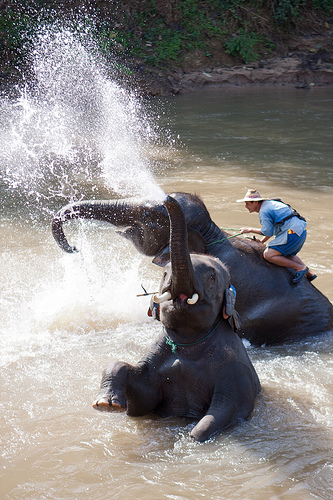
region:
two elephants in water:
[35, 184, 330, 442]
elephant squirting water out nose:
[0, 5, 271, 441]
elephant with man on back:
[38, 184, 332, 344]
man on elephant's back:
[238, 180, 319, 283]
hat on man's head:
[237, 187, 270, 203]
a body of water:
[187, 98, 328, 172]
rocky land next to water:
[185, 65, 331, 88]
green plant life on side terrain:
[146, 22, 205, 61]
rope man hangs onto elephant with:
[208, 220, 243, 241]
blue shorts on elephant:
[273, 232, 308, 252]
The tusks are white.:
[147, 289, 206, 312]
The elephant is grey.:
[112, 229, 260, 437]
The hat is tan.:
[232, 179, 270, 209]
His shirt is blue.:
[254, 200, 303, 245]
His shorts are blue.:
[263, 219, 306, 255]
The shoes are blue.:
[287, 264, 316, 284]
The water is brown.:
[10, 363, 332, 497]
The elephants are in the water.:
[43, 170, 312, 438]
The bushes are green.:
[7, 4, 322, 64]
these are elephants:
[10, 101, 326, 355]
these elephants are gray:
[78, 190, 246, 395]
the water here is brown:
[40, 420, 161, 496]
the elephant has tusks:
[164, 283, 201, 301]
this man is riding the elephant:
[226, 194, 322, 295]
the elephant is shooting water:
[53, 158, 185, 215]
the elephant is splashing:
[52, 244, 179, 360]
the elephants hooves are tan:
[92, 399, 125, 418]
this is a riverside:
[83, 14, 307, 119]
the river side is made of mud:
[186, 58, 311, 87]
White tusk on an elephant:
[145, 283, 177, 312]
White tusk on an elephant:
[189, 288, 210, 321]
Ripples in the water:
[10, 472, 57, 495]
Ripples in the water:
[63, 467, 92, 497]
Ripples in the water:
[115, 467, 132, 492]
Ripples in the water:
[171, 464, 242, 499]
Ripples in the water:
[263, 424, 293, 463]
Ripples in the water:
[276, 391, 325, 452]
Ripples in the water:
[284, 348, 332, 389]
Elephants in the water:
[24, 166, 327, 445]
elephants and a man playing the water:
[25, 170, 320, 447]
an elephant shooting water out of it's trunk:
[87, 170, 266, 449]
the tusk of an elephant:
[180, 289, 203, 303]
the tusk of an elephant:
[148, 287, 171, 304]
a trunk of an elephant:
[48, 188, 121, 251]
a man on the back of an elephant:
[236, 171, 321, 283]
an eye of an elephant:
[203, 260, 218, 283]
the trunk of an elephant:
[158, 188, 195, 288]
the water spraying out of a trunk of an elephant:
[23, 73, 169, 218]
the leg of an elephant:
[93, 353, 159, 420]